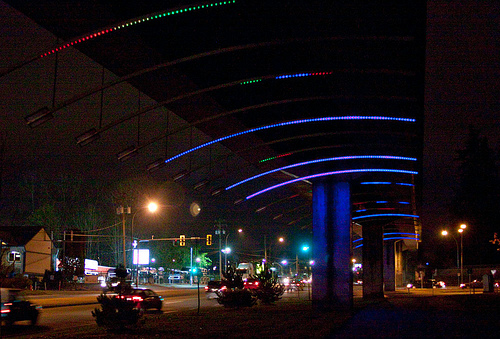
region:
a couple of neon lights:
[223, 146, 420, 203]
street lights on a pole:
[439, 221, 466, 245]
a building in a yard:
[1, 224, 64, 281]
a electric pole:
[117, 199, 131, 267]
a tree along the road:
[210, 264, 255, 314]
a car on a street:
[118, 284, 161, 309]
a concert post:
[304, 182, 361, 309]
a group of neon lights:
[322, 92, 409, 249]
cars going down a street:
[199, 273, 301, 302]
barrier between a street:
[50, 285, 99, 314]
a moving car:
[121, 282, 163, 308]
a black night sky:
[414, 0, 494, 218]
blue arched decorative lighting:
[145, 110, 416, 165]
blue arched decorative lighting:
[223, 153, 414, 200]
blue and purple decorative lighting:
[243, 165, 413, 217]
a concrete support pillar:
[310, 175, 350, 301]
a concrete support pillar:
[358, 218, 383, 294]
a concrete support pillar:
[381, 236, 392, 291]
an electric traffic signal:
[170, 235, 175, 246]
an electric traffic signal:
[178, 232, 188, 247]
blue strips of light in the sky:
[165, 113, 458, 253]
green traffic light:
[297, 239, 319, 256]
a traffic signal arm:
[126, 225, 215, 253]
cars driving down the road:
[0, 252, 264, 337]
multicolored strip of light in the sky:
[235, 65, 342, 91]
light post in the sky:
[440, 217, 474, 292]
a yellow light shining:
[137, 193, 165, 220]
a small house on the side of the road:
[2, 221, 62, 295]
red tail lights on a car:
[111, 294, 152, 303]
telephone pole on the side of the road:
[114, 193, 136, 293]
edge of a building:
[347, 251, 359, 296]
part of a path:
[307, 285, 320, 312]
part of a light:
[143, 247, 157, 258]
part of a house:
[33, 233, 57, 241]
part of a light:
[296, 231, 311, 264]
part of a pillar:
[338, 248, 359, 270]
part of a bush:
[235, 276, 238, 289]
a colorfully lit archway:
[36, 0, 447, 322]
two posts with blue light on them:
[305, 177, 353, 309]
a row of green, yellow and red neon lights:
[25, 1, 238, 67]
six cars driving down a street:
[0, 262, 305, 336]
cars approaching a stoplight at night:
[0, 72, 497, 336]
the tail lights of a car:
[242, 277, 259, 289]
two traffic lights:
[135, 232, 218, 247]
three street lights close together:
[437, 219, 468, 289]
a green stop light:
[295, 240, 315, 254]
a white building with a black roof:
[0, 222, 60, 287]